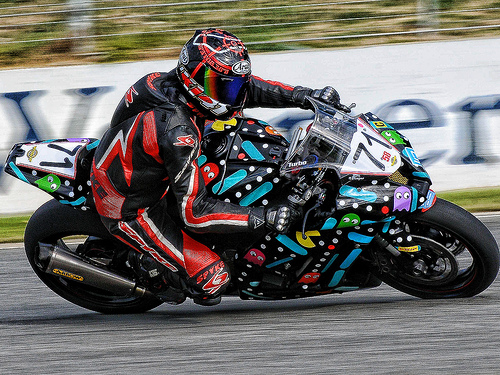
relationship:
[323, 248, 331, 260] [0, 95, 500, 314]
dot on dot motorcycle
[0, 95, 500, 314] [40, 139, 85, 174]
dot motorcycle has number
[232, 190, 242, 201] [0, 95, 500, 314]
dot on dot motorcycle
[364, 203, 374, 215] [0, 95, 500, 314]
dot on dot motorcycle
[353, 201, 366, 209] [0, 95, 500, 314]
dot on dot motorcycle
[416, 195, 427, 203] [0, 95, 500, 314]
dot on dot motorcycle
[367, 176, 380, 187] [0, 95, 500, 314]
dot on dot motorcycle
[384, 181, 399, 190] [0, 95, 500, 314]
dot on dot motorcycle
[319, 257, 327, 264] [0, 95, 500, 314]
dot on dot motorcycle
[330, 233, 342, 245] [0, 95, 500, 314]
dot on dot motorcycle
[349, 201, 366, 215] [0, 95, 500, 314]
white dot on dot motorcycle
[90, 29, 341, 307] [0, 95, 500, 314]
motorcyclist decorating dot motorcycle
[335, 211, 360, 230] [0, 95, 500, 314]
ghost on dot motorcycle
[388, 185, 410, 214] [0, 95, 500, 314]
ghost on dot motorcycle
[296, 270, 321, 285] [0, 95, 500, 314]
ghost on dot motorcycle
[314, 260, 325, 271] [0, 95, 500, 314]
dot on dot motorcycle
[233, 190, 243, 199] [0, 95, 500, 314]
dot on dot motorcycle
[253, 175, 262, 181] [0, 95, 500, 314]
dot on dot motorcycle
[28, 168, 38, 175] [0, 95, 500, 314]
dot on dot motorcycle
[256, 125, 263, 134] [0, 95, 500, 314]
dot on dot motorcycle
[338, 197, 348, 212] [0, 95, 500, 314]
white dot on dot motorcycle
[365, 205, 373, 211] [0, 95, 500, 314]
dot on dot motorcycle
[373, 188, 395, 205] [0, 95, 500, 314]
dot motorcycle on dot motorcycle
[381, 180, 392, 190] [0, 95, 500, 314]
dot on dot motorcycle